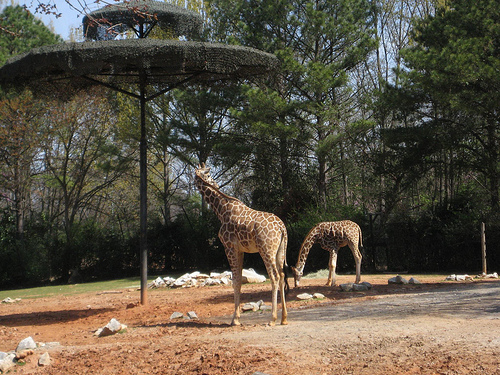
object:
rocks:
[151, 276, 166, 289]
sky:
[43, 0, 84, 30]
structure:
[1, 20, 275, 96]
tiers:
[75, 2, 213, 42]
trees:
[151, 64, 189, 277]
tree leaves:
[438, 54, 466, 84]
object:
[7, 7, 284, 307]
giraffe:
[291, 219, 364, 285]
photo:
[2, 1, 495, 371]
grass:
[19, 288, 73, 295]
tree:
[1, 71, 41, 253]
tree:
[48, 114, 105, 285]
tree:
[185, 78, 237, 229]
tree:
[297, 52, 337, 220]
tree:
[371, 57, 399, 269]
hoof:
[267, 320, 278, 327]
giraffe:
[193, 161, 289, 328]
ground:
[3, 273, 500, 375]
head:
[290, 264, 306, 287]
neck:
[189, 174, 238, 220]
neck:
[295, 223, 321, 273]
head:
[192, 165, 221, 188]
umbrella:
[0, 2, 275, 312]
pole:
[133, 76, 153, 312]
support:
[145, 71, 205, 102]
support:
[77, 73, 140, 101]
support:
[124, 16, 159, 38]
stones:
[93, 316, 128, 338]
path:
[198, 273, 499, 365]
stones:
[168, 310, 186, 320]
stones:
[242, 299, 265, 312]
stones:
[291, 289, 332, 301]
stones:
[338, 282, 355, 292]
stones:
[387, 275, 410, 285]